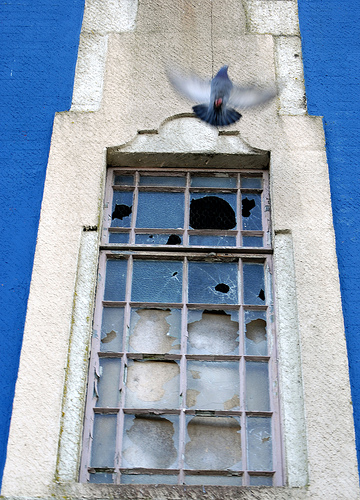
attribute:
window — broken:
[90, 174, 260, 315]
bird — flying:
[159, 54, 272, 129]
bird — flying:
[149, 61, 246, 150]